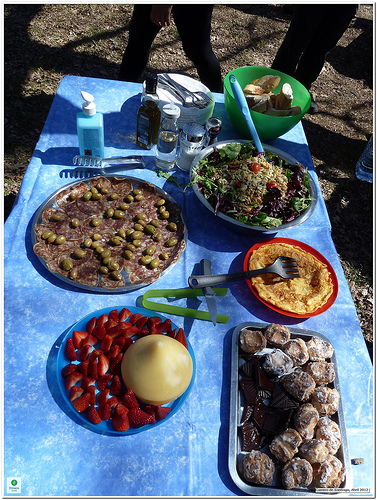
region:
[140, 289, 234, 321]
a pair of green tongs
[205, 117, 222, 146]
a pepper shaker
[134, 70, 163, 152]
a large bottle with a black top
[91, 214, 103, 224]
a light green olive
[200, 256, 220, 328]
a large black and silver knife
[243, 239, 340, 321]
a red plate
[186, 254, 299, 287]
a large black fork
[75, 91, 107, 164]
a blue and white soap pump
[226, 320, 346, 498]
a large silver pan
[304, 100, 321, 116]
part of a person's shoe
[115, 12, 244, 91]
someone walking by a table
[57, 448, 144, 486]
a blue tablecloth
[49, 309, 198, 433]
strawberries on a blue plate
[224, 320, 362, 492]
dessert on a tray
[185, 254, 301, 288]
a large black serving fork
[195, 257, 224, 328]
a sharp knife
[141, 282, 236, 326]
green serving tongs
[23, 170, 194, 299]
green olives on a tray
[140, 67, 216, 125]
white plates and silverware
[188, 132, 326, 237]
salad in a bowl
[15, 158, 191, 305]
a pizza on a pan.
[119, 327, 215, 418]
a mountain of dipping sauce.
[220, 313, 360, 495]
a metal tray of cookies.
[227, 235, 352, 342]
food in a red pan.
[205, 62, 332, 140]
a green bowl on a table.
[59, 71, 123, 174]
a blue container of soap.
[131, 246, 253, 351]
a pair of green tongs.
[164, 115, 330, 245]
a green salad in a bowl.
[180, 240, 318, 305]
a metal cooking utensil.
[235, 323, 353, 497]
a tray of cookies.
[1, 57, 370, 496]
the tablecloth is blue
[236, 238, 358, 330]
food in a red bowl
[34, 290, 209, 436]
food in a blue bowl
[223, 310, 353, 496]
the pan is silver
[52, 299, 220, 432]
the strawberries are red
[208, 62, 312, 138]
food in a green bowl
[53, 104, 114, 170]
liquid in a blue bottle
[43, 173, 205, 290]
green food in the pan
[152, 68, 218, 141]
the plates are white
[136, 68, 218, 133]
the plates are paper plates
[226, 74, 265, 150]
a long blue spoon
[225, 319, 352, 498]
a long silver tray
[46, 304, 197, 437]
a blue plate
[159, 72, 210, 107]
large silver tongs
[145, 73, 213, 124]
a stack of white paper plates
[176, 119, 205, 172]
a glass salt shaker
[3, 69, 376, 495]
a blue and white tablecloth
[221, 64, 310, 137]
a large green bowl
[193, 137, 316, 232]
a large bowl of salad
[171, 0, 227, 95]
the leg of a person